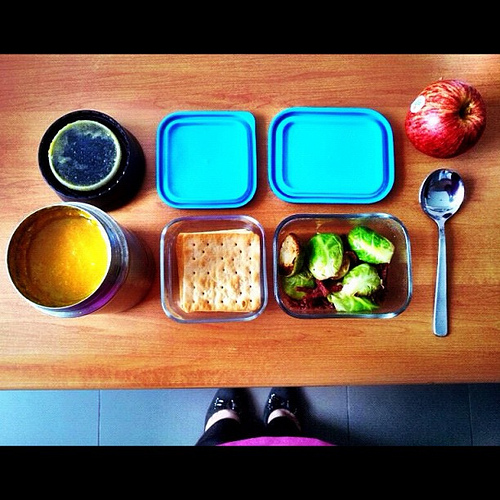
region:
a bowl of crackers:
[153, 207, 269, 328]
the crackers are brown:
[152, 210, 275, 330]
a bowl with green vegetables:
[269, 209, 417, 326]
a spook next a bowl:
[417, 162, 471, 343]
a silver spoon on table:
[413, 163, 468, 343]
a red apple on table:
[401, 71, 492, 167]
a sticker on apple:
[404, 83, 435, 119]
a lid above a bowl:
[269, 103, 421, 326]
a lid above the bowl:
[149, 103, 274, 329]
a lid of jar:
[3, 102, 150, 329]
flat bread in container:
[172, 230, 261, 315]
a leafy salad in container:
[285, 228, 397, 308]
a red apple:
[405, 80, 483, 152]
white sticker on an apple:
[408, 95, 425, 111]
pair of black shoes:
[204, 388, 300, 418]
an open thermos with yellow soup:
[10, 205, 155, 320]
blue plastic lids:
[154, 105, 395, 209]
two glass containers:
[158, 213, 413, 324]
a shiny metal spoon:
[419, 171, 468, 338]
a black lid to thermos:
[37, 110, 144, 210]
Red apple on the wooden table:
[415, 80, 482, 159]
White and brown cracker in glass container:
[179, 238, 259, 310]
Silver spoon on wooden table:
[421, 169, 467, 336]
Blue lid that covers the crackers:
[161, 108, 257, 215]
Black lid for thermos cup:
[36, 109, 126, 202]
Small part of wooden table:
[163, 358, 185, 375]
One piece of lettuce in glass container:
[351, 226, 392, 262]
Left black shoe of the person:
[208, 390, 245, 409]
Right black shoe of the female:
[263, 388, 298, 405]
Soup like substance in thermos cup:
[48, 240, 78, 272]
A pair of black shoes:
[201, 382, 306, 429]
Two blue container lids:
[155, 99, 396, 215]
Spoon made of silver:
[415, 163, 471, 342]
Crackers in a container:
[154, 209, 271, 325]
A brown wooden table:
[1, 54, 498, 389]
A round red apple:
[401, 73, 489, 161]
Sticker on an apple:
[404, 90, 429, 118]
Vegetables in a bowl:
[268, 208, 413, 322]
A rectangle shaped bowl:
[270, 209, 415, 328]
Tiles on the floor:
[1, 383, 498, 446]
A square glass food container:
[159, 210, 268, 327]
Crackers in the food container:
[174, 230, 261, 315]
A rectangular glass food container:
[269, 210, 413, 321]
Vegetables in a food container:
[281, 222, 402, 314]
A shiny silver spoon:
[418, 165, 469, 339]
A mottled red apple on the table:
[404, 77, 486, 159]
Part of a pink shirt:
[209, 433, 332, 447]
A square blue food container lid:
[156, 105, 261, 212]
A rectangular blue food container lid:
[261, 105, 397, 207]